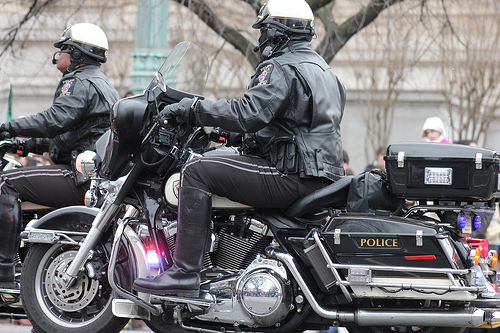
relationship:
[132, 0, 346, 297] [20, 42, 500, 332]
officer on motorcycle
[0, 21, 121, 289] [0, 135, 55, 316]
officer on motorcycle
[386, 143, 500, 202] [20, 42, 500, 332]
case on motorcycle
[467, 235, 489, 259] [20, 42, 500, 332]
tail-light on motorcycle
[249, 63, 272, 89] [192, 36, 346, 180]
patch on jacket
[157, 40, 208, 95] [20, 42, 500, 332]
windshield on motorcycle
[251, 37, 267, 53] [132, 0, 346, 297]
headset on officer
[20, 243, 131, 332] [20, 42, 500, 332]
front-tire on motorcycle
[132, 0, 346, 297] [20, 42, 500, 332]
officer sitting on h motorcycle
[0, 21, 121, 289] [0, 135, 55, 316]
officer sitting on h motorcycle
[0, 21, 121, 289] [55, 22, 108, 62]
officer wearing helmet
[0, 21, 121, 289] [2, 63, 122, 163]
officer wearing jacket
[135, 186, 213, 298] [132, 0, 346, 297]
boot worn by officer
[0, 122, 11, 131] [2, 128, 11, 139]
hand grabbing handle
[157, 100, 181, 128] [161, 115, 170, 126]
hand grabbing handle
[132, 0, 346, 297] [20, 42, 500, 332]
officer sitting on motorcycle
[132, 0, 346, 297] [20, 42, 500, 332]
officer driving on motorcycle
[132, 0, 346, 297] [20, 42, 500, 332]
officer riding on motorcycle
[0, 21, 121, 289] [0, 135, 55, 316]
officer riding on motorcycle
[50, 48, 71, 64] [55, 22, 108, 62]
headset on helmet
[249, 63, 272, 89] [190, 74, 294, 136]
patch on sleeve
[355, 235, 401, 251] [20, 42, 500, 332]
word on motorcycle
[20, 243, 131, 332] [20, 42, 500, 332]
front-tire of motorcycle